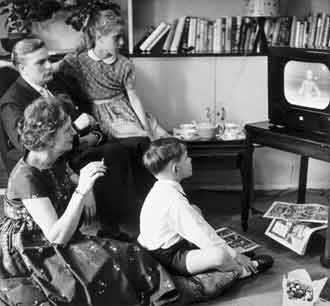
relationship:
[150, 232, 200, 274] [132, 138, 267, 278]
shorts on boy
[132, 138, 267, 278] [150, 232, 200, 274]
boy wears shorts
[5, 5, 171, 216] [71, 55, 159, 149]
girl wearing dress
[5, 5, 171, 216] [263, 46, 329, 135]
girl watching tv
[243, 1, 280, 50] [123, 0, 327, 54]
small lamp on book shelf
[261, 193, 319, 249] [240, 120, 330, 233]
newspaper on shelf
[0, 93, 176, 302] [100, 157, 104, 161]
woman holding cigarette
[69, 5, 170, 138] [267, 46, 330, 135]
girl watching television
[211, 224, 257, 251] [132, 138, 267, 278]
newspaper in lap of boy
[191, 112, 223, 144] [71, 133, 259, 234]
pitcher on table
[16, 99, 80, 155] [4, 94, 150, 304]
hair of woman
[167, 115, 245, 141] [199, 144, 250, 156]
cups on table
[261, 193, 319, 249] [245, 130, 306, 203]
newspaper on shelf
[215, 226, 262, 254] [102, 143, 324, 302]
newspaper on floor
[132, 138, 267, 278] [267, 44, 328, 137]
boy watching tv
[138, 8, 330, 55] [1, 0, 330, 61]
books leaning on book shelf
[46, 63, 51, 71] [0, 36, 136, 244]
nose on man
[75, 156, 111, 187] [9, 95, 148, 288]
hand on woman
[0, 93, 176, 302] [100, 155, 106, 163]
woman with cigarette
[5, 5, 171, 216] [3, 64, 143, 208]
girl on chair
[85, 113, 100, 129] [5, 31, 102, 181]
cigratte with man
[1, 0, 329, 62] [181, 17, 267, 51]
book shelf with books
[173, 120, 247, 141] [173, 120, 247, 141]
cups with cups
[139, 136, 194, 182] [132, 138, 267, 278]
head on boy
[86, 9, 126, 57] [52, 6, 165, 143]
head on girl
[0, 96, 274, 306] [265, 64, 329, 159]
woman watching television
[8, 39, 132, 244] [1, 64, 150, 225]
man in chair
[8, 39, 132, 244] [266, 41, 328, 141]
man with television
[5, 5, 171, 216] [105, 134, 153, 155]
girl on arm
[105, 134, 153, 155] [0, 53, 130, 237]
arm on chair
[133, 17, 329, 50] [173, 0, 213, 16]
books on wall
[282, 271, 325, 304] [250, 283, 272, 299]
container on floor